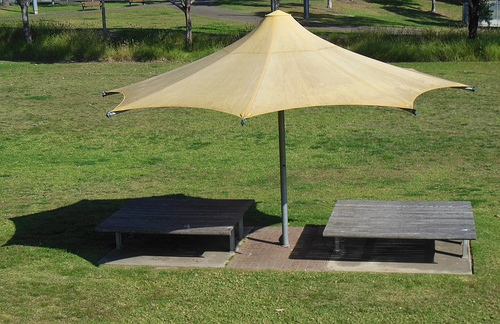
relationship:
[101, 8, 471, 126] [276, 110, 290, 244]
umbrella on post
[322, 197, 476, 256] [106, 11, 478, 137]
platform under umbrella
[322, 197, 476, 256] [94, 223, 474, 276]
platform on patio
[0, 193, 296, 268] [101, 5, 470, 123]
shadow of umbrella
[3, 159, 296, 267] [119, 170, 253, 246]
shadow of table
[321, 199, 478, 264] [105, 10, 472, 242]
platform by umbrella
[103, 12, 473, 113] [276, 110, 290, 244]
umbrella on post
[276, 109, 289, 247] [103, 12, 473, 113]
pole holding umbrella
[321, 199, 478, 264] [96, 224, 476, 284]
platform on concrete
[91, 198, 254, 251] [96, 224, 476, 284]
platforms on concrete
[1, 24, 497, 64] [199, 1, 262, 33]
grass by road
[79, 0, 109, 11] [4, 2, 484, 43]
bench in background